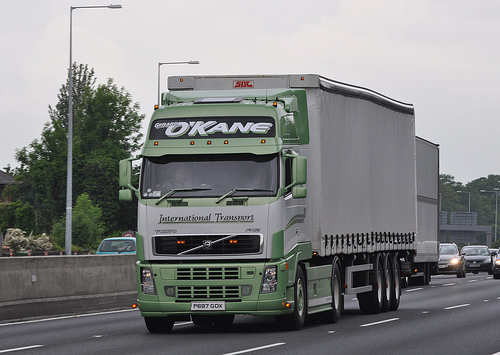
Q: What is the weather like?
A: It is cloudy.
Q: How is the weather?
A: It is cloudy.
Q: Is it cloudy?
A: Yes, it is cloudy.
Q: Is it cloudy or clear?
A: It is cloudy.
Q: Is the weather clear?
A: No, it is cloudy.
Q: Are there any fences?
A: No, there are no fences.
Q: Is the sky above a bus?
A: No, the sky is above the truck.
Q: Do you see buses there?
A: No, there are no buses.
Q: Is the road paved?
A: Yes, the road is paved.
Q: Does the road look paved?
A: Yes, the road is paved.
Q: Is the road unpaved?
A: No, the road is paved.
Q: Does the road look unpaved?
A: No, the road is paved.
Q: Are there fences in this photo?
A: No, there are no fences.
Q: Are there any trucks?
A: Yes, there is a truck.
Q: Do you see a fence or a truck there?
A: Yes, there is a truck.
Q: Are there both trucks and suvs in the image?
A: No, there is a truck but no suvs.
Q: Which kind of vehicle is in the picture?
A: The vehicle is a truck.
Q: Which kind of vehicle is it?
A: The vehicle is a truck.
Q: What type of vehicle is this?
A: This is a truck.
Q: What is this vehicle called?
A: This is a truck.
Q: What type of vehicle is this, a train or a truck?
A: This is a truck.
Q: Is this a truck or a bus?
A: This is a truck.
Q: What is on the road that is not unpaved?
A: The truck is on the road.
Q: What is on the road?
A: The truck is on the road.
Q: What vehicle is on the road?
A: The vehicle is a truck.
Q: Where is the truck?
A: The truck is on the road.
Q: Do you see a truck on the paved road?
A: Yes, there is a truck on the road.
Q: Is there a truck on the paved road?
A: Yes, there is a truck on the road.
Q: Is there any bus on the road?
A: No, there is a truck on the road.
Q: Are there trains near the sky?
A: No, there is a truck near the sky.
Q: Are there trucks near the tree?
A: Yes, there is a truck near the tree.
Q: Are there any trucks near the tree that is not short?
A: Yes, there is a truck near the tree.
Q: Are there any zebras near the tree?
A: No, there is a truck near the tree.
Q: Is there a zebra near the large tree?
A: No, there is a truck near the tree.